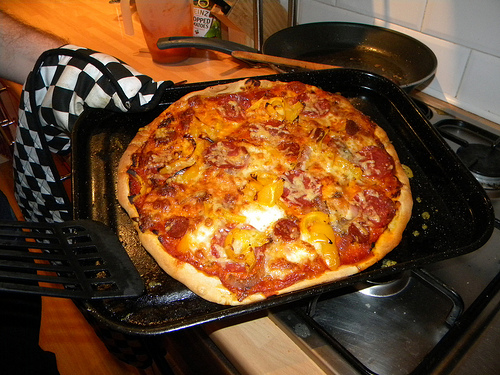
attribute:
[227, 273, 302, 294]
tomato sauce — red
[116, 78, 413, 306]
pizza — freshly baked, cooked, uncut, baked, round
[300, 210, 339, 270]
peppers — yellow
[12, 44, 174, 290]
oven mitt — checkered, black, white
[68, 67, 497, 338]
pan — cast iron, black, rectangular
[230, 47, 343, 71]
utensil — wooden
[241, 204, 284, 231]
cheese — melted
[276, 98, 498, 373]
oven top — gas-operated, black, silver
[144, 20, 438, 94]
frying pan — black, dirty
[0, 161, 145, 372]
floor — light brown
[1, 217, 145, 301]
spatula — black, large, plastic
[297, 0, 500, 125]
wall — tiled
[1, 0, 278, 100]
counter — wood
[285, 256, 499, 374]
burner — black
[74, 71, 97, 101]
square — black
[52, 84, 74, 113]
square — black